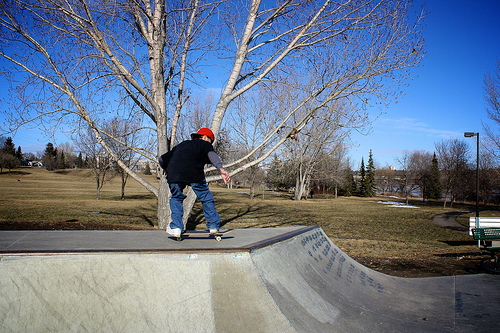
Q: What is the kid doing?
A: Skateboarding.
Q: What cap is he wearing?
A: Red.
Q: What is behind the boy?
A: A tree.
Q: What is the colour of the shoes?
A: White.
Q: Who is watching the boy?
A: No one.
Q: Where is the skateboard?
A: On the slab.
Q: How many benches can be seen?
A: One.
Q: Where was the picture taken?
A: Park.